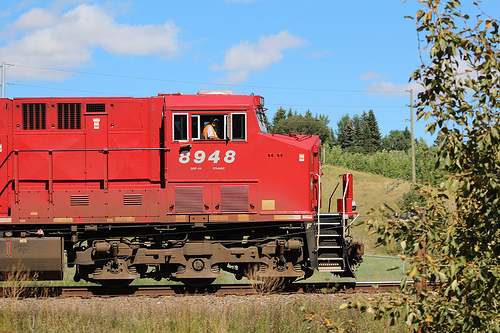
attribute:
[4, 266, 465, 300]
tracks — brown, black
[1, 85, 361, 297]
train — red, wide, moving, big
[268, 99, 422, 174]
trees — green, tall, wide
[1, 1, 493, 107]
sky — blue, light blue, open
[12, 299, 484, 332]
grass — green, high, thick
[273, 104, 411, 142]
leaves — green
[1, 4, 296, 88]
clouds — thin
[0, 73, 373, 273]
train — red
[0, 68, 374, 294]
engine — red